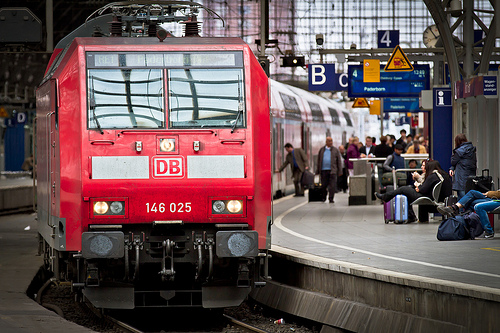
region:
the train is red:
[25, 12, 400, 311]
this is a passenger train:
[30, 12, 413, 302]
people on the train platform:
[283, 99, 495, 265]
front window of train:
[69, 37, 236, 143]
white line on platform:
[276, 192, 493, 302]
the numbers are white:
[142, 187, 199, 218]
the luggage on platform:
[380, 190, 427, 250]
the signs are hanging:
[320, 35, 445, 120]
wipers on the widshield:
[85, 96, 242, 126]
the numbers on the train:
[136, 198, 207, 225]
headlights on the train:
[88, 200, 246, 217]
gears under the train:
[87, 257, 264, 302]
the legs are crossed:
[455, 192, 494, 237]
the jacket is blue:
[452, 142, 481, 193]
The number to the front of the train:
[144, 187, 194, 219]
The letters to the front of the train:
[144, 155, 194, 182]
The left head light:
[82, 190, 128, 226]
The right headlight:
[207, 192, 257, 229]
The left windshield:
[86, 72, 163, 137]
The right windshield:
[171, 57, 249, 133]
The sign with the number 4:
[370, 25, 410, 55]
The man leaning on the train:
[274, 130, 319, 193]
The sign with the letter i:
[429, 77, 455, 110]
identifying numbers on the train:
[141, 198, 199, 213]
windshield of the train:
[87, 50, 243, 130]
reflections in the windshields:
[85, 51, 244, 129]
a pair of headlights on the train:
[92, 198, 128, 215]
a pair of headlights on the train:
[208, 199, 244, 215]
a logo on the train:
[155, 158, 182, 177]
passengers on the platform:
[278, 135, 343, 201]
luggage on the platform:
[384, 192, 411, 221]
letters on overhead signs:
[304, 63, 352, 91]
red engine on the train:
[35, 38, 275, 316]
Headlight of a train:
[227, 198, 243, 215]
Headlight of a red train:
[225, 197, 245, 215]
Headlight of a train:
[91, 199, 111, 217]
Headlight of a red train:
[91, 198, 111, 215]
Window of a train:
[86, 69, 164, 127]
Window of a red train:
[86, 69, 163, 127]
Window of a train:
[168, 69, 243, 126]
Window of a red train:
[167, 68, 246, 125]